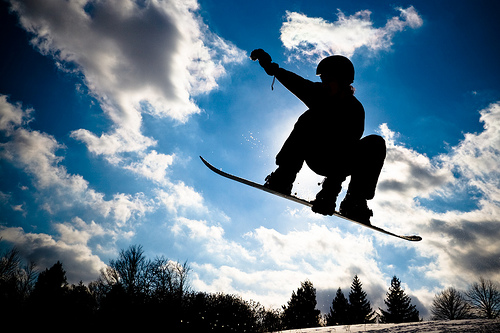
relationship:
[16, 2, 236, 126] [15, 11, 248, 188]
section of clouds